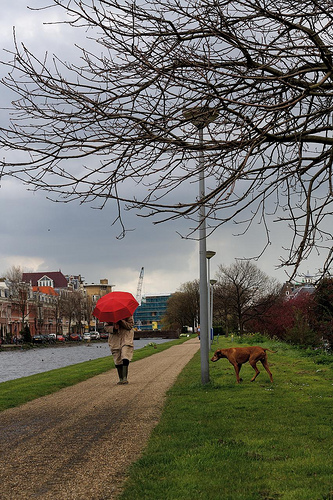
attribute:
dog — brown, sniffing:
[204, 332, 280, 381]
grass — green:
[189, 417, 299, 455]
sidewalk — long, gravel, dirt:
[31, 397, 116, 426]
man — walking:
[92, 286, 141, 387]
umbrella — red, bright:
[81, 279, 133, 324]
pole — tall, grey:
[164, 82, 217, 386]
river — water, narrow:
[17, 346, 68, 360]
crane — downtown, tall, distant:
[127, 259, 152, 297]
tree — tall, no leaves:
[221, 152, 228, 276]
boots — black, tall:
[114, 375, 138, 385]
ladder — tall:
[143, 277, 166, 306]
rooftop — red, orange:
[92, 280, 106, 289]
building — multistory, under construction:
[140, 291, 183, 327]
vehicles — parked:
[15, 337, 85, 338]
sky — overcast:
[38, 32, 104, 68]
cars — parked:
[27, 327, 91, 349]